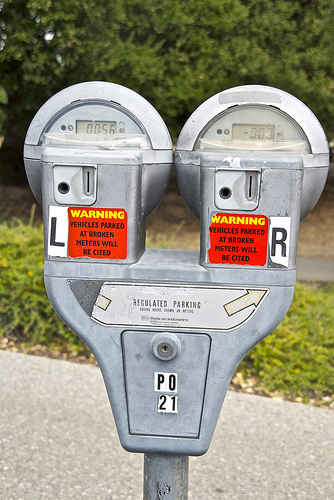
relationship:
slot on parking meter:
[86, 170, 91, 193] [21, 81, 174, 265]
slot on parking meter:
[248, 176, 253, 197] [174, 84, 330, 268]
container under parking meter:
[41, 250, 296, 455] [21, 81, 174, 265]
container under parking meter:
[41, 250, 296, 455] [174, 84, 330, 268]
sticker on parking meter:
[66, 207, 128, 262] [21, 81, 174, 265]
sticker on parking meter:
[206, 210, 268, 267] [174, 84, 330, 268]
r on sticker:
[272, 227, 285, 258] [267, 216, 291, 268]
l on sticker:
[50, 216, 65, 248] [45, 205, 70, 257]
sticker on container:
[154, 372, 177, 413] [41, 250, 296, 455]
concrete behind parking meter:
[0, 350, 332, 499] [21, 81, 174, 265]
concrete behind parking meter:
[0, 350, 332, 499] [174, 84, 330, 268]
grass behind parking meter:
[1, 224, 83, 349] [21, 81, 174, 265]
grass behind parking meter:
[239, 282, 333, 397] [174, 84, 330, 268]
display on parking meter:
[76, 120, 118, 134] [21, 81, 174, 265]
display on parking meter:
[230, 124, 275, 141] [174, 84, 330, 268]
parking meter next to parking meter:
[21, 81, 174, 265] [174, 84, 330, 268]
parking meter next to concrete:
[21, 81, 174, 265] [0, 350, 332, 499]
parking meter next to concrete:
[174, 84, 330, 268] [0, 350, 332, 499]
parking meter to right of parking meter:
[174, 84, 330, 268] [21, 81, 174, 265]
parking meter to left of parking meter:
[21, 81, 174, 265] [174, 84, 330, 268]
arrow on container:
[223, 290, 268, 317] [41, 250, 296, 455]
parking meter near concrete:
[21, 81, 174, 265] [0, 350, 332, 499]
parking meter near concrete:
[174, 84, 330, 268] [0, 350, 332, 499]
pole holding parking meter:
[142, 451, 190, 498] [21, 81, 174, 265]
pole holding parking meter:
[142, 451, 190, 498] [174, 84, 330, 268]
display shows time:
[76, 120, 118, 134] [100, 124, 114, 135]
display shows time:
[230, 124, 275, 141] [265, 127, 274, 139]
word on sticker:
[69, 209, 127, 221] [66, 207, 128, 262]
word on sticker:
[212, 214, 267, 228] [206, 210, 268, 267]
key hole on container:
[156, 344, 173, 359] [41, 250, 296, 455]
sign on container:
[93, 283, 271, 334] [41, 250, 296, 455]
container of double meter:
[41, 250, 296, 455] [24, 81, 330, 456]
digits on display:
[249, 127, 265, 142] [230, 124, 275, 141]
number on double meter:
[158, 394, 176, 412] [24, 81, 330, 456]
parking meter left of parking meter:
[21, 81, 174, 265] [174, 84, 330, 268]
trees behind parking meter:
[0, 2, 332, 155] [21, 81, 174, 265]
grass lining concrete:
[1, 224, 83, 349] [0, 350, 332, 499]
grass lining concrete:
[239, 282, 333, 397] [0, 350, 332, 499]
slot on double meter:
[86, 170, 91, 193] [24, 81, 330, 456]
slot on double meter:
[248, 176, 253, 197] [24, 81, 330, 456]